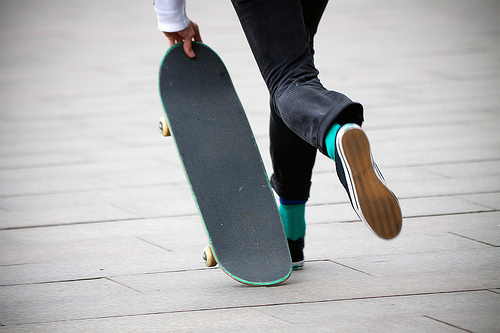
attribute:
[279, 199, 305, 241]
sock —  blue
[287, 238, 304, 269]
sneaker —   black and white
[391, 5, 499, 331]
blocks —  pavement,  rectangle shaped ,  cement ,  gray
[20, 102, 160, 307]
sidewalk —  tile brick,  gray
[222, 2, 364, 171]
pants —  black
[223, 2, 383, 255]
legs —  skateboarder's 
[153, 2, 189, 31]
shirt —  long sleeve,  white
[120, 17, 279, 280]
skateboard —  SOMEONE's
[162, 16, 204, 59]
left hand — the left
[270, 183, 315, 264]
socks —  AQUA colored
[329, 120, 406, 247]
foot —  the right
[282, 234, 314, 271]
shoe —  black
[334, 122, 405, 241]
sneaker —  black and white  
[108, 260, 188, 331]
cement —  gray,  rectangle 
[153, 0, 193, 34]
shirt sleeve — long, white 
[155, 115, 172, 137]
yellow wheel —  SKATEBOARD's,  YELLOW,  TWO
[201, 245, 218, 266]
yellow wheel —  SKATEBOARD's,  YELLOW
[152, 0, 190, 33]
cuff —  sweater's,  white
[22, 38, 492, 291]
sidewalk — light gray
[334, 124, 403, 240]
shoe — converse 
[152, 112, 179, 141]
wheel — yellow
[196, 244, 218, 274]
wheel — yellow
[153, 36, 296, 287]
skateboard — WOODEN,  black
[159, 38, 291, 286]
rim —  GREEN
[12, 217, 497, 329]
brick ground — brick 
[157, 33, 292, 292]
trim —  green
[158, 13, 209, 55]
hand — the left,   person's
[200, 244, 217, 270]
wheel — white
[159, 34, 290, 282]
top — black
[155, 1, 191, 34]
shirt —  white